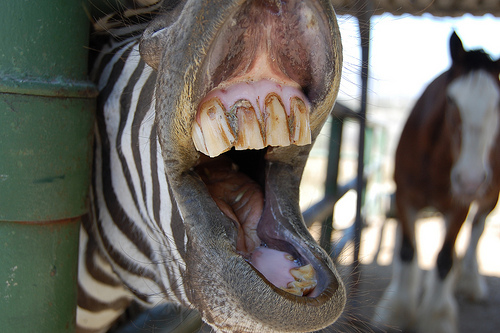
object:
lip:
[161, 0, 339, 115]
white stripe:
[107, 144, 122, 204]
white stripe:
[137, 132, 150, 174]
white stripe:
[90, 276, 105, 300]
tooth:
[226, 95, 267, 152]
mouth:
[171, 3, 347, 308]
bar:
[0, 2, 107, 328]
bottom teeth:
[288, 262, 317, 294]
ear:
[446, 33, 466, 66]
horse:
[368, 28, 498, 333]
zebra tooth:
[190, 100, 236, 159]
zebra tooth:
[262, 95, 290, 148]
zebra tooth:
[289, 95, 312, 146]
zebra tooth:
[289, 264, 315, 281]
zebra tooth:
[281, 284, 303, 296]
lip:
[188, 226, 347, 333]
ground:
[359, 254, 382, 275]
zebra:
[78, 0, 347, 331]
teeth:
[188, 94, 312, 158]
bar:
[357, 134, 365, 172]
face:
[442, 64, 498, 217]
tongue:
[209, 173, 263, 250]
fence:
[121, 92, 376, 332]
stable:
[0, 0, 499, 332]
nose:
[456, 173, 491, 193]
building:
[3, 6, 90, 332]